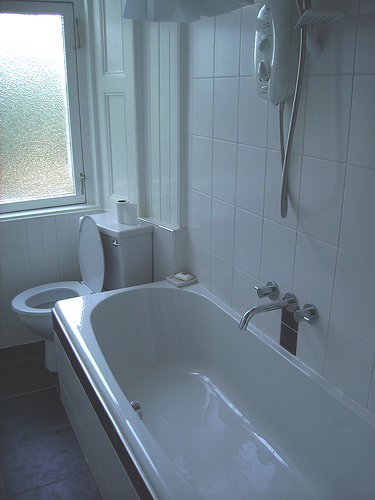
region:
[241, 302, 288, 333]
A silver faucet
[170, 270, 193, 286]
A bar of soap on the bathub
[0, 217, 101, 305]
A clean toilet in the corner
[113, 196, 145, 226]
Toilet paper on the toilet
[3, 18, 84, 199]
A bright window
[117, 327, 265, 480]
A spotless bathtub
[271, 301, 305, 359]
Two black tiles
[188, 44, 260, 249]
The bathroom walls are white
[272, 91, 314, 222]
A silver hose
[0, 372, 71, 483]
The floor is grey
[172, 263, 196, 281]
bar of white soap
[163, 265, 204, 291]
white soap dish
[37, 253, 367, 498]
large white bathtub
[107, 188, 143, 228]
half empty roll of toilet paper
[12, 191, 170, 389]
plain white toilet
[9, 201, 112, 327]
the lid is open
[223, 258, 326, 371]
hot and cold knobs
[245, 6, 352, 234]
shower attachment with controls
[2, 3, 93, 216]
translucent privacy window window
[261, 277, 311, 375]
two gray tiles on the wall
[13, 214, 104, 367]
a white porcelain toilet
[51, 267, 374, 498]
a white porcelain bath tub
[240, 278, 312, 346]
a chrome bath tub faucet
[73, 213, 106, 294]
an open toilet seat lid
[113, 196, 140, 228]
a roll of toilet paper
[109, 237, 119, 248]
a toilet seat flush handle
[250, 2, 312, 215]
a flexible shower head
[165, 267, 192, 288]
a dish with soap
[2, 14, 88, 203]
a frosted glass window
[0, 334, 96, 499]
a black tile floor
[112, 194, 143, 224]
toilet paper on back of toilet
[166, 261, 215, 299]
soap in the soap dish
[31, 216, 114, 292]
toilet seat is up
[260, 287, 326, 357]
black tile by faucet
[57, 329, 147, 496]
black tile along tub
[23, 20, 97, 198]
window in the bathroom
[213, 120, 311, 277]
white tile on the wall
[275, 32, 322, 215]
cord for the shower head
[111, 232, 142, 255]
handle on the toilet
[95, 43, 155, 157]
wall is white wood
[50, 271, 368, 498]
the big bath tub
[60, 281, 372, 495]
the deep bath tub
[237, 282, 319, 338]
the bath tub water fixtures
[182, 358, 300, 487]
the reflection in the tub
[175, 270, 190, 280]
the soap on a dish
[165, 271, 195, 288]
the soap dish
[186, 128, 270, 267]
the tiled white wall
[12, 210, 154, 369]
the white toilet bowl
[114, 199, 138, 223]
the roll of toilet paper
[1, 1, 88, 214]
the window in the bathroom